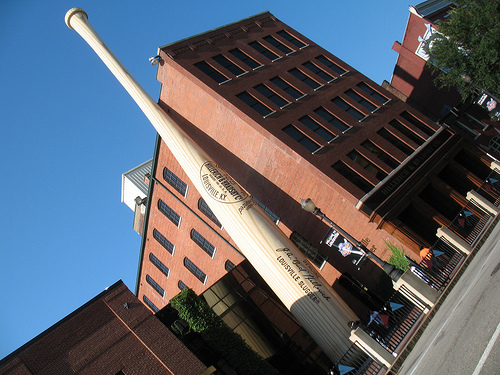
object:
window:
[388, 118, 425, 143]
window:
[378, 128, 414, 153]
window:
[361, 138, 400, 166]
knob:
[54, 1, 94, 29]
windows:
[328, 95, 366, 124]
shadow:
[312, 263, 415, 370]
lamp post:
[311, 207, 406, 281]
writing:
[272, 237, 334, 312]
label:
[187, 153, 263, 218]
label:
[270, 239, 343, 309]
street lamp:
[434, 218, 500, 309]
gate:
[386, 196, 469, 268]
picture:
[3, 4, 498, 374]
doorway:
[393, 202, 458, 259]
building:
[118, 5, 498, 370]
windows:
[139, 271, 170, 298]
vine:
[160, 296, 275, 362]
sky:
[0, 2, 428, 364]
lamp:
[299, 192, 321, 217]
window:
[265, 67, 310, 101]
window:
[398, 110, 440, 137]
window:
[191, 56, 230, 86]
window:
[155, 194, 184, 232]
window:
[195, 194, 228, 229]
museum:
[125, 7, 499, 355]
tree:
[415, 0, 500, 111]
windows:
[179, 251, 208, 285]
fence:
[238, 187, 496, 373]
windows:
[233, 86, 276, 120]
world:
[0, 0, 499, 374]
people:
[419, 244, 450, 275]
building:
[3, 278, 215, 375]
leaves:
[189, 322, 195, 326]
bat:
[61, 3, 366, 368]